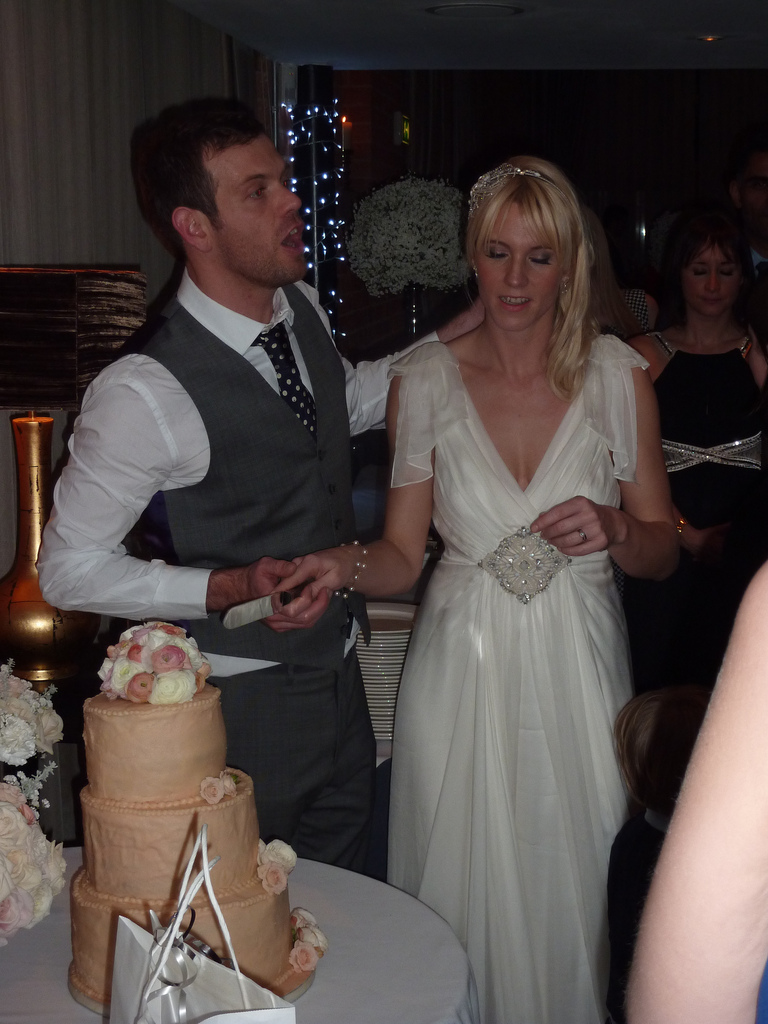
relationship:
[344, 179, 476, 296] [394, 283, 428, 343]
bush in vase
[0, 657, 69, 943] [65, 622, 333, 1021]
floral arrangement near cake